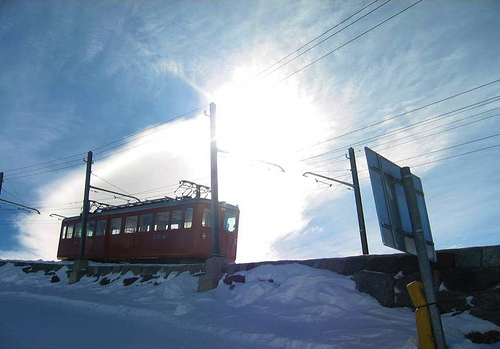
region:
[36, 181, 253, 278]
trolley train on a track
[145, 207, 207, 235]
windows on side of train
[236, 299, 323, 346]
white snow on ground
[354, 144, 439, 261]
back of a sign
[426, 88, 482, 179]
electrical wires above tracks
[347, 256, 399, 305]
boulder in the snow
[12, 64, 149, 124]
clouds in the sky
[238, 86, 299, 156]
sunlight shining through clouds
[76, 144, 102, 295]
utility pole by tracks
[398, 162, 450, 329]
metal pole of a sign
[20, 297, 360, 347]
ground covered in snow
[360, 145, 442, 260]
back side of a sign connected to a pole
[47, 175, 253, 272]
red tram car with no passengers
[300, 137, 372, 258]
tram line pole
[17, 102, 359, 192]
electric tram car wires connected to poles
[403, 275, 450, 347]
orange object attached to sign post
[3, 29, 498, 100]
scattered clouds in a blue sky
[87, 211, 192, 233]
windows of red tram car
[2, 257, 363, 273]
snow covered border of tram way tracks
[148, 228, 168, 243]
white letters on the side of tram car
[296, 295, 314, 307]
part of the snow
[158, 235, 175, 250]
part of a train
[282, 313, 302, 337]
edge of a post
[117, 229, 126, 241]
side of a train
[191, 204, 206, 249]
edge of a train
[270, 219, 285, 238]
part of a cloud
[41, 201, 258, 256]
A red tram car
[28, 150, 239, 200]
A tram car line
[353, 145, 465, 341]
A white sign on metal pole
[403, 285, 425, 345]
A metal sign pole attached to a yellow pole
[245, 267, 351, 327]
White snow on embankment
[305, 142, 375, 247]
Pole with electric lines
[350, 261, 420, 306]
Large rocks or boulders on side of track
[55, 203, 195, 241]
A row of glass windows in tram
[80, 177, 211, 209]
A tram with line attachements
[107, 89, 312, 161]
Bright light behind tram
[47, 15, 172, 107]
Bright blue sky above the train.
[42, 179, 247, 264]
Red train on the tracks.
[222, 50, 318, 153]
Sun breaking through the clouds.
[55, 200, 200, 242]
Red train with many windows.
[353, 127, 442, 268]
A sign along side the tracks.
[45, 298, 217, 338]
Snow on the ground.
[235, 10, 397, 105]
Phone wires above the tracks.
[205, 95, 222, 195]
Telephone pole beside the train.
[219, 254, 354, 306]
Pile of snow beside the tracks.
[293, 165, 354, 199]
Lights on the pole.